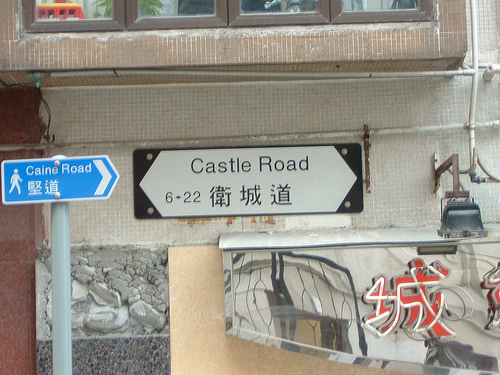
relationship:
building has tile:
[11, 23, 498, 262] [375, 85, 405, 106]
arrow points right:
[93, 159, 113, 195] [411, 11, 471, 373]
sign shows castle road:
[135, 113, 392, 237] [185, 150, 315, 177]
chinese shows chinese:
[360, 257, 466, 340] [350, 242, 467, 353]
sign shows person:
[0, 154, 122, 207] [5, 165, 25, 195]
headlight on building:
[437, 197, 488, 238] [2, 0, 499, 373]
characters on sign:
[207, 182, 302, 212] [115, 133, 363, 245]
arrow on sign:
[88, 154, 108, 188] [0, 154, 122, 207]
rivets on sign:
[52, 158, 62, 198] [9, 146, 119, 208]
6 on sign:
[163, 189, 175, 206] [133, 141, 363, 221]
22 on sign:
[181, 190, 201, 205] [133, 141, 363, 221]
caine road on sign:
[26, 160, 92, 176] [129, 129, 359, 231]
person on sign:
[7, 168, 24, 194] [1, 156, 118, 203]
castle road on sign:
[192, 156, 309, 172] [133, 141, 363, 221]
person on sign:
[7, 169, 24, 196] [2, 152, 123, 224]